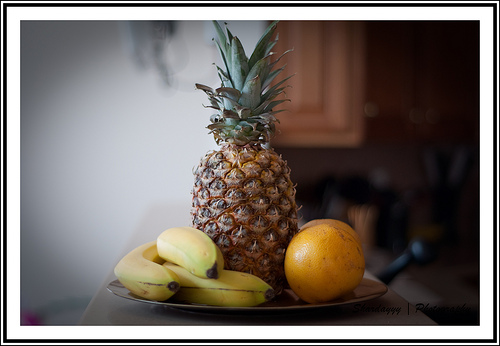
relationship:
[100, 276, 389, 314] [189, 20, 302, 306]
plate full of fruits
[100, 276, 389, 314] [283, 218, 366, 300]
plate full of orange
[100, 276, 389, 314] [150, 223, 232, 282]
plate full of fruit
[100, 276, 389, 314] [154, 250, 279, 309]
plate full of fruit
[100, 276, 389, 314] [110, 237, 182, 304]
plate full of fruit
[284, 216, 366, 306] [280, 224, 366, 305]
group contains orange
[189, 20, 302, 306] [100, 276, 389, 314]
fruits on plate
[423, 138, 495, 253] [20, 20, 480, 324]
utensils in background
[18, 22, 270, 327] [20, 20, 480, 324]
wall in background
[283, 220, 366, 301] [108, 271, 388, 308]
orange on plate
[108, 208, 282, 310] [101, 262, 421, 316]
banana on plate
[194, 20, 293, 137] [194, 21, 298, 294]
top of pineapple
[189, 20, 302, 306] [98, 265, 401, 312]
fruits on plate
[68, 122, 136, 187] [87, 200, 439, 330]
wall behind counter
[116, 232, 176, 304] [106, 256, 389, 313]
banana on plate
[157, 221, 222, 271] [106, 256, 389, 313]
banana on plate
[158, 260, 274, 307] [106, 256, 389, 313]
banana on plate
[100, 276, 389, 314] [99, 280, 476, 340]
plate on counter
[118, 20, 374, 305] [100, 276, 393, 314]
fruits on plate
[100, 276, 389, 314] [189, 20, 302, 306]
plate under fruits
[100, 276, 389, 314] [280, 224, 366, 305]
plate under orange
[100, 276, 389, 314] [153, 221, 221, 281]
plate under banana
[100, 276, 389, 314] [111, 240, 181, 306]
plate under banana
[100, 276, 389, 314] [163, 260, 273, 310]
plate under fruit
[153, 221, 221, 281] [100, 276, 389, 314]
banana on plate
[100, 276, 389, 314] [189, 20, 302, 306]
plate with fruits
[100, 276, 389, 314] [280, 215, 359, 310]
plate with fruit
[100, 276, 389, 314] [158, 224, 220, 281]
plate with fruit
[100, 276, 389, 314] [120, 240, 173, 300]
plate with fruit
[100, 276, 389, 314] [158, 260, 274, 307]
plate with banana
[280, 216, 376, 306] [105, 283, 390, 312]
orange on plate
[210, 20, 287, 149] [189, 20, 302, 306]
leaves on top of fruits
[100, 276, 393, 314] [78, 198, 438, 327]
plate on countertop